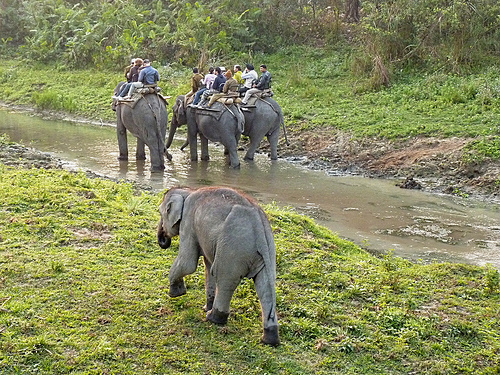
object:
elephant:
[152, 185, 282, 345]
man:
[122, 59, 159, 99]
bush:
[64, 19, 100, 68]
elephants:
[110, 82, 177, 174]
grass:
[0, 163, 498, 375]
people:
[237, 62, 270, 104]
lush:
[330, 190, 421, 235]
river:
[0, 106, 499, 269]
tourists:
[204, 68, 240, 112]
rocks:
[398, 175, 423, 190]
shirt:
[136, 67, 161, 85]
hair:
[193, 67, 199, 73]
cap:
[260, 64, 268, 72]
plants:
[0, 166, 499, 374]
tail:
[258, 250, 278, 320]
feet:
[165, 284, 187, 300]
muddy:
[370, 186, 475, 249]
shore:
[0, 108, 80, 153]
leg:
[165, 241, 198, 299]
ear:
[162, 193, 186, 229]